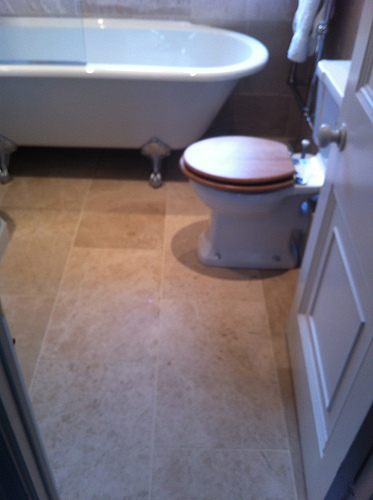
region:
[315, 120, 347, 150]
silver door knob on door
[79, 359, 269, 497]
marbled ceramic tile on floor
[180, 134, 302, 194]
toilet seat made of wood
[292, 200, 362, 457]
indented door panel on door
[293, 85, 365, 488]
open white bathroom door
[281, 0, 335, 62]
white towel on rack against the wall.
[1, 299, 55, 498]
door frame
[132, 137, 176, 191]
silver leg on pedestal bath tub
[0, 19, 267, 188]
white porcelain pedestal tub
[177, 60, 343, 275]
toilet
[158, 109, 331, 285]
a white toilet with a wooden seat and lid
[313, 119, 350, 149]
a white door knob on a white door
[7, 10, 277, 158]
a white pedestal legged bathtub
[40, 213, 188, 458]
a cream colored ceramic floor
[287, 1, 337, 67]
a white towel hanging on a towel rack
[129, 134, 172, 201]
a silver leg on the bathtub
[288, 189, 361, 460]
the lower half of a white door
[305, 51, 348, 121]
a white toilet tank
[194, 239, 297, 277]
the bolts that affix the toilet to the floor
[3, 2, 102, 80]
a glass spray shield on the edge of the tub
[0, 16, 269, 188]
claw foot bathtub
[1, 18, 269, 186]
bathtub is white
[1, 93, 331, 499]
tile floor under bathtub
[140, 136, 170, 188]
metal claw foot on bathtub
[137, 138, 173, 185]
claw foot is silver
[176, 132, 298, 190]
brown wooden toilet seat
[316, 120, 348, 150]
silver metal door knob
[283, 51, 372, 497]
white bathroom door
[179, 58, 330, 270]
white toilet next to bathtub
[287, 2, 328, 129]
white towel on silver towel rack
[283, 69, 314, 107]
silver pipe in bathroom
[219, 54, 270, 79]
white edge of bathtub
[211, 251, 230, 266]
large bolt in white bathroom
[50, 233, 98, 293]
tan lines on bathroom floor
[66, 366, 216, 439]
artisan tile on floor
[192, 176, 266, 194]
wood base on toilet seat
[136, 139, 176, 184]
white Victorian base on bathtub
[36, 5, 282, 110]
large shiny white bath tub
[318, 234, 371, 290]
grooves in white door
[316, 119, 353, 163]
brown door handle on door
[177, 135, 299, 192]
wooden toilet seat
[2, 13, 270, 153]
white porcelain lion foot bath tub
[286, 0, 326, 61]
white cotton bath towel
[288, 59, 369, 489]
white bathroom door with white door knob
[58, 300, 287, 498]
Tan ceramic floor tiles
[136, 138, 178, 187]
Silver lion foot for tub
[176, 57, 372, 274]
White toilet with wooden seat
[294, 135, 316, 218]
Silver toilet plunger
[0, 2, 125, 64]
Clear shower curtain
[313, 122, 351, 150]
white metal door knob